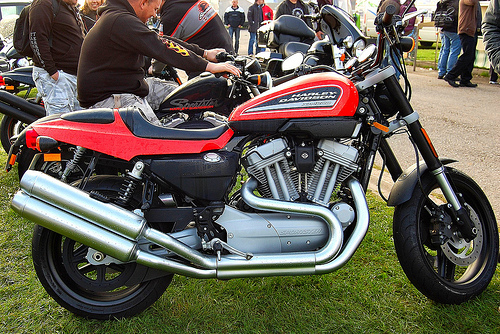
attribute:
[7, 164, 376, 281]
pipe — silver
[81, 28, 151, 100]
shirt — brown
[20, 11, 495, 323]
motorcycle — black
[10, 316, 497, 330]
grass — green 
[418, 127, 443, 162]
light — orange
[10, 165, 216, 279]
exhaust — silver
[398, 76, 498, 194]
road — light, brownish, gray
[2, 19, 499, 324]
bike — parked, red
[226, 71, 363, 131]
tank — red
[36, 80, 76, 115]
pants — white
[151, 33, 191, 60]
logo — flame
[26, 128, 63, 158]
light — red